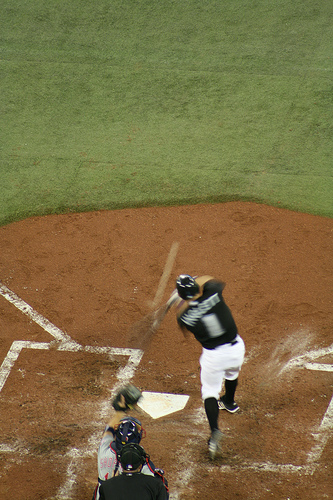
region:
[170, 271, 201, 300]
man wearing black helmet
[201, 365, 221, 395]
man wearing white pants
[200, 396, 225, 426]
man wearing black socks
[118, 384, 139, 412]
black mitt on mans hand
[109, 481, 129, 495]
man wearing black vest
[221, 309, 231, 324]
man wearing black shirt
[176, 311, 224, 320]
white lettering on shirt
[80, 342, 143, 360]
white lines on field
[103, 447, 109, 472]
man wearing grey shirt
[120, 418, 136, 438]
man wearing blue helmet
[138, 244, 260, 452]
the player is hitting the ball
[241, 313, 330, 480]
white lines on the dirt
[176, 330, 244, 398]
the pants are white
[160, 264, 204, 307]
the player is wearing a helmet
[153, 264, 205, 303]
the helmet is black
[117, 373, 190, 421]
home base is white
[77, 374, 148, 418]
the catcher`s glove is black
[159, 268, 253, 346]
the number on the shirt is 1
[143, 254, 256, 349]
the bat is in motion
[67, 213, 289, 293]
footprints in the dirt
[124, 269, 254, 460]
Player in black and white uniform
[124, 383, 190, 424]
Base is white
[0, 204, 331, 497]
White lines on home mound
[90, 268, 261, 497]
umpire, catcher, and hitter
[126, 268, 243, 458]
Hitter in swinging motion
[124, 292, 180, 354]
Bat in motion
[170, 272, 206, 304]
Black helmet on player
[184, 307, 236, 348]
number one on jersey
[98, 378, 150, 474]
Catcher has glove up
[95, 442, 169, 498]
Umpire watching baseball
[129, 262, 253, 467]
a man swinging a bat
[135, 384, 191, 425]
home base is in the red clay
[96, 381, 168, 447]
the catcher is catching a baseball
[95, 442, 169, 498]
an umpire is behind the catcher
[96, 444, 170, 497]
the umpire is wearing black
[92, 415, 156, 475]
the catcher has a baseball uniform on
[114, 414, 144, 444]
the catcher is wearing head protection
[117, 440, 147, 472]
the umpire is wearing head protection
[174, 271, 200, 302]
the batter is wearing a protective helmet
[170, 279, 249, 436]
the batter is wearing a black and white uniform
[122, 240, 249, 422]
The baseball player is swinging the bat.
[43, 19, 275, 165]
An open green field.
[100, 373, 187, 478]
The catcher is trying to catch the ball.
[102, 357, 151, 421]
The player is wearing a glove.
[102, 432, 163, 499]
The umpire stands behind the player.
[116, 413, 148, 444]
The player has on a helmet with mask.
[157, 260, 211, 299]
The helmet is black.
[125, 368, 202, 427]
The player is standing near home base.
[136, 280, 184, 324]
The player has a bat in his hand.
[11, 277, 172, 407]
White lines are drawn by home plate.